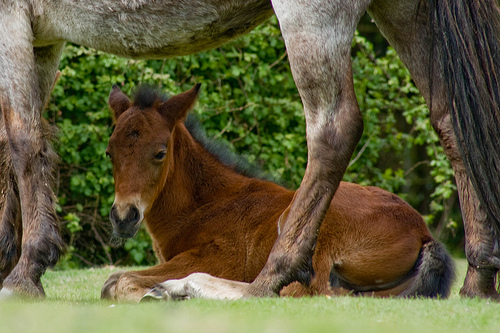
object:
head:
[105, 80, 203, 239]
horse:
[0, 0, 499, 303]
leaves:
[242, 106, 254, 116]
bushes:
[47, 12, 465, 271]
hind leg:
[176, 205, 362, 298]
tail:
[422, 0, 498, 237]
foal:
[100, 83, 456, 301]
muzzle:
[108, 205, 143, 239]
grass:
[0, 258, 499, 332]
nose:
[108, 205, 140, 222]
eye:
[153, 148, 170, 163]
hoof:
[0, 268, 47, 300]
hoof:
[245, 263, 308, 298]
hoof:
[459, 265, 498, 298]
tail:
[402, 238, 456, 298]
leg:
[0, 115, 20, 277]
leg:
[267, 0, 370, 282]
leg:
[362, 0, 498, 275]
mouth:
[108, 226, 142, 238]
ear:
[159, 82, 201, 122]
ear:
[108, 82, 128, 120]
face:
[106, 119, 173, 229]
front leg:
[0, 4, 57, 279]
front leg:
[114, 248, 213, 301]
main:
[133, 78, 273, 184]